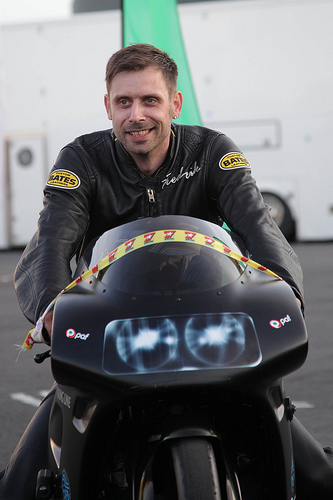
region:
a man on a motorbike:
[1, 37, 332, 498]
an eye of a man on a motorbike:
[142, 96, 156, 108]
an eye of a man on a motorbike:
[115, 96, 131, 107]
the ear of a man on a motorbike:
[169, 91, 187, 120]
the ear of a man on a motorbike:
[98, 95, 113, 120]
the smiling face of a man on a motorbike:
[101, 45, 184, 153]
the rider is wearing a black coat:
[11, 39, 310, 360]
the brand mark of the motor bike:
[63, 317, 92, 347]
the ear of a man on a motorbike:
[263, 311, 295, 330]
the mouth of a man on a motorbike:
[120, 124, 161, 141]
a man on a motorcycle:
[10, 42, 309, 323]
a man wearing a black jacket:
[15, 42, 305, 306]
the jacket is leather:
[18, 117, 306, 321]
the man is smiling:
[113, 121, 160, 140]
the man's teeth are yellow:
[121, 123, 156, 140]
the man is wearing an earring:
[172, 113, 181, 126]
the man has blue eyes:
[110, 92, 160, 108]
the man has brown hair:
[98, 41, 177, 88]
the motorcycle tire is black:
[147, 428, 241, 498]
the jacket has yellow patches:
[43, 159, 85, 201]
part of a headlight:
[192, 324, 234, 356]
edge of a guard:
[175, 422, 207, 442]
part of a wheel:
[182, 461, 207, 498]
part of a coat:
[23, 295, 40, 310]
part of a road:
[0, 366, 14, 380]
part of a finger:
[43, 317, 48, 328]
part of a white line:
[15, 392, 34, 409]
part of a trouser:
[289, 420, 309, 452]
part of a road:
[305, 319, 323, 359]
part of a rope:
[20, 327, 34, 342]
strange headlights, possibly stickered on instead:
[102, 311, 264, 370]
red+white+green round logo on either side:
[64, 327, 75, 338]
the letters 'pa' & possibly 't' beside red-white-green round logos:
[72, 330, 90, 342]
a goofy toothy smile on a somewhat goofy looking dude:
[124, 124, 152, 137]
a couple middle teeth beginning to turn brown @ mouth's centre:
[133, 127, 141, 135]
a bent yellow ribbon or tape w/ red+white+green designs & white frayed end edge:
[6, 227, 300, 363]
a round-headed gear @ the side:
[30, 344, 52, 364]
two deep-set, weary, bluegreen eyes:
[113, 93, 155, 106]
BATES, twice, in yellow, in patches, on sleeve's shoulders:
[39, 150, 248, 189]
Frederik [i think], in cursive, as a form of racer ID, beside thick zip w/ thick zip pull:
[155, 155, 212, 195]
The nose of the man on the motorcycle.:
[127, 109, 146, 126]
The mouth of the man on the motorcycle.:
[125, 127, 157, 138]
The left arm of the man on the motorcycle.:
[21, 152, 83, 300]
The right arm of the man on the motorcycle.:
[217, 147, 304, 308]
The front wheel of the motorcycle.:
[157, 439, 223, 499]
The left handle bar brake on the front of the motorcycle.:
[28, 351, 55, 362]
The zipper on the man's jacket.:
[141, 181, 156, 205]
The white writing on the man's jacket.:
[161, 170, 205, 183]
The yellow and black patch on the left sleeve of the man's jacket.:
[47, 169, 83, 188]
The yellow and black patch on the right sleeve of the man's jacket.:
[219, 153, 254, 171]